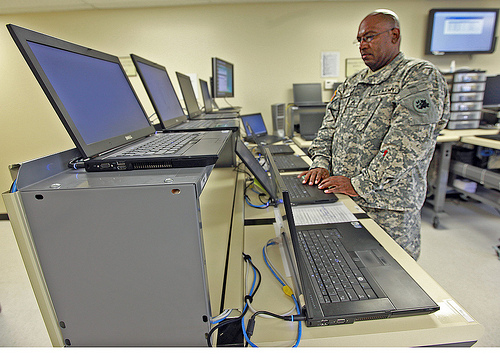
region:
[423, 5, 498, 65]
flat screen monitor on wall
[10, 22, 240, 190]
row of black laptops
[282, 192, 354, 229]
white piece of paper laying on desk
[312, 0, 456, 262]
man in military uniform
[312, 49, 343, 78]
white sign hanging on wall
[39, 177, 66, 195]
silver metal bolt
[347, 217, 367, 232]
windows logo on black laptop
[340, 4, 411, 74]
man in pair of eye glasses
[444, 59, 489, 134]
stack of plastic drawers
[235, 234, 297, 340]
laptop cords behind laptop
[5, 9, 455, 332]
a military man overseeing a bunch of laptops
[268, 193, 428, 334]
a very thick laptop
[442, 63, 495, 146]
a stack of plastic drawers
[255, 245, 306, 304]
a blue CAT cable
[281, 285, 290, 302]
yellow electrical tape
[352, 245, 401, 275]
a track pad for a mouse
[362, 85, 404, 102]
a nametag for this man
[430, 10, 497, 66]
a tv mounted on the wall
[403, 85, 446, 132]
a patch on a uniform sleeve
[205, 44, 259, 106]
a slightly raised computer monitor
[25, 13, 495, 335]
The man is a room with computers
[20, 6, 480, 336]
The man is wearing a uniform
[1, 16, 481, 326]
A man is employed by the military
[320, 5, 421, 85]
The man is wearing nice eyeglasses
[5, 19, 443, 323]
Set of laptops on the table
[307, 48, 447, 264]
Solfier's uniform worn by man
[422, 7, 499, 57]
LED TV on the wall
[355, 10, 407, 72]
Head of the man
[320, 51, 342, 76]
White paper hanging on the wall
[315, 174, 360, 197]
left hand of the man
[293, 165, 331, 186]
right hand of the man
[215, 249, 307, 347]
black charger on the laptop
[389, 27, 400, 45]
left ear of the man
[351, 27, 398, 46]
Glasses worn by the man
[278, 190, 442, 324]
The laptop sits on the counter.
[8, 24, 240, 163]
A row of laptops sit on the stand.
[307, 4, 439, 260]
A military member looks at the computer.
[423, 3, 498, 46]
A TV sits on the wall.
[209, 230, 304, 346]
Colored wires provide power.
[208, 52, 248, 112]
A desktop sits in the back ground.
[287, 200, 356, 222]
A paper is on the desk.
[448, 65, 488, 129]
A storage bin on the table.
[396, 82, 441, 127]
The military member's patches.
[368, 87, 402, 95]
The uniform name tag.